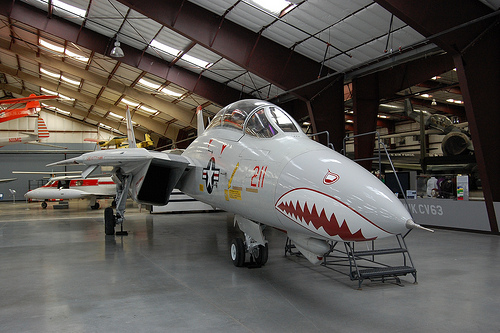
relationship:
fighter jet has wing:
[43, 99, 435, 266] [45, 145, 188, 166]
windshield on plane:
[207, 98, 301, 140] [52, 79, 432, 264]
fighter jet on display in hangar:
[43, 99, 435, 266] [6, 7, 484, 327]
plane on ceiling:
[1, 86, 61, 126] [1, 1, 490, 146]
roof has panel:
[3, 7, 498, 152] [247, 0, 296, 17]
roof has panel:
[3, 7, 498, 152] [151, 35, 213, 73]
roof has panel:
[3, 7, 498, 152] [133, 77, 175, 101]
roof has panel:
[3, 7, 498, 152] [114, 97, 155, 122]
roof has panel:
[3, 7, 498, 152] [39, 61, 82, 90]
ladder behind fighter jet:
[281, 212, 423, 287] [43, 99, 435, 266]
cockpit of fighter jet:
[213, 100, 293, 142] [43, 99, 428, 268]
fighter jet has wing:
[43, 99, 435, 266] [46, 146, 193, 206]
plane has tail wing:
[2, 116, 58, 143] [31, 112, 48, 137]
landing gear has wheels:
[229, 217, 274, 272] [228, 233, 268, 268]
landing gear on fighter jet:
[229, 217, 274, 272] [43, 99, 435, 266]